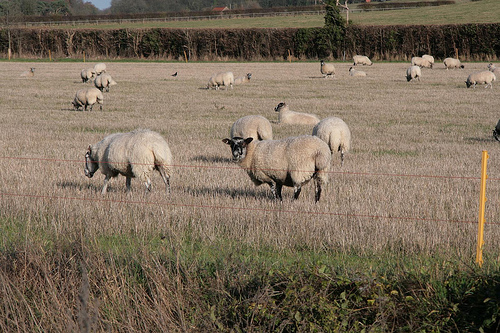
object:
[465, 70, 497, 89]
sheep